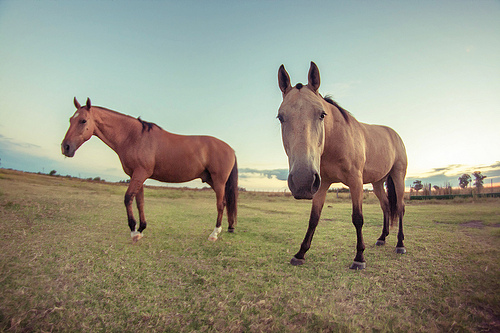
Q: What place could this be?
A: It is a field.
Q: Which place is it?
A: It is a field.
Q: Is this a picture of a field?
A: Yes, it is showing a field.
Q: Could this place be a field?
A: Yes, it is a field.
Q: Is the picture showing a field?
A: Yes, it is showing a field.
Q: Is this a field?
A: Yes, it is a field.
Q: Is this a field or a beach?
A: It is a field.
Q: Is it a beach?
A: No, it is a field.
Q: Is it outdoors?
A: Yes, it is outdoors.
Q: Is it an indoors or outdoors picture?
A: It is outdoors.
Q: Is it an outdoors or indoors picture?
A: It is outdoors.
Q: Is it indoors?
A: No, it is outdoors.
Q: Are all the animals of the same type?
A: Yes, all the animals are horses.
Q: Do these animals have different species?
A: No, all the animals are horses.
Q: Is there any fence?
A: No, there are no fences.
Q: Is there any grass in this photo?
A: Yes, there is grass.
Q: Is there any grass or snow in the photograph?
A: Yes, there is grass.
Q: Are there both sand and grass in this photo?
A: No, there is grass but no sand.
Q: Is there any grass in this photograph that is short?
A: Yes, there is short grass.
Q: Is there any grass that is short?
A: Yes, there is grass that is short.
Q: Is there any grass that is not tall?
A: Yes, there is short grass.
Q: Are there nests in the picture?
A: No, there are no nests.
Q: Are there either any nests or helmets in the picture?
A: No, there are no nests or helmets.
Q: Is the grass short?
A: Yes, the grass is short.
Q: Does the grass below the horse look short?
A: Yes, the grass is short.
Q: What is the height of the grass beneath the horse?
A: The grass is short.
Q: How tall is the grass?
A: The grass is short.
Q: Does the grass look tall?
A: No, the grass is short.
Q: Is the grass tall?
A: No, the grass is short.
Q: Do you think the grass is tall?
A: No, the grass is short.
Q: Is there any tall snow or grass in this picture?
A: No, there is grass but it is short.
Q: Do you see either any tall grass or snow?
A: No, there is grass but it is short.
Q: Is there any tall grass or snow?
A: No, there is grass but it is short.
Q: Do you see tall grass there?
A: No, there is grass but it is short.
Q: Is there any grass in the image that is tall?
A: No, there is grass but it is short.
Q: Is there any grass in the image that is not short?
A: No, there is grass but it is short.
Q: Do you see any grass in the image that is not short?
A: No, there is grass but it is short.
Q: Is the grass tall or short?
A: The grass is short.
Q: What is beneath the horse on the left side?
A: The grass is beneath the horse.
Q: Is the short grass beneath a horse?
A: Yes, the grass is beneath a horse.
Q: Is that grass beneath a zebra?
A: No, the grass is beneath a horse.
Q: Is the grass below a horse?
A: Yes, the grass is below a horse.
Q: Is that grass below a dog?
A: No, the grass is below a horse.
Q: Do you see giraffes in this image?
A: No, there are no giraffes.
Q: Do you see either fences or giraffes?
A: No, there are no giraffes or fences.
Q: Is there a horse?
A: Yes, there is a horse.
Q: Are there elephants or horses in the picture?
A: Yes, there is a horse.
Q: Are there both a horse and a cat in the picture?
A: No, there is a horse but no cats.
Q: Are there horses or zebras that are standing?
A: Yes, the horse is standing.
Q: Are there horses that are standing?
A: Yes, there is a horse that is standing.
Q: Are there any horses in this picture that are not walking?
A: Yes, there is a horse that is standing.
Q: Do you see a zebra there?
A: No, there are no zebras.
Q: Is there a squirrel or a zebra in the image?
A: No, there are no zebras or squirrels.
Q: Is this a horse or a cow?
A: This is a horse.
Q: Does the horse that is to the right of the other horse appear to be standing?
A: Yes, the horse is standing.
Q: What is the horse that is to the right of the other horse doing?
A: The horse is standing.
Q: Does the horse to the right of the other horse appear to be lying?
A: No, the horse is standing.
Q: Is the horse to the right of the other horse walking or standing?
A: The horse is standing.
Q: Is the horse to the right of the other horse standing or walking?
A: The horse is standing.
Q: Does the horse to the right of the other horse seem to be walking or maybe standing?
A: The horse is standing.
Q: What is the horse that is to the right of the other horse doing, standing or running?
A: The horse is standing.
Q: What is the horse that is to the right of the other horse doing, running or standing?
A: The horse is standing.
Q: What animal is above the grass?
A: The animal is a horse.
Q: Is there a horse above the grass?
A: Yes, there is a horse above the grass.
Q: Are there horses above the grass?
A: Yes, there is a horse above the grass.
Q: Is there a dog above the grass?
A: No, there is a horse above the grass.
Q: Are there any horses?
A: Yes, there are horses.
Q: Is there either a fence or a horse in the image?
A: Yes, there are horses.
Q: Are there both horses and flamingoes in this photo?
A: No, there are horses but no flamingoes.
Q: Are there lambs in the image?
A: No, there are no lambs.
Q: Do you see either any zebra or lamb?
A: No, there are no lambs or zebras.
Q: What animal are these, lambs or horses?
A: These are horses.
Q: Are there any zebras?
A: No, there are no zebras.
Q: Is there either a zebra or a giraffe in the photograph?
A: No, there are no zebras or giraffes.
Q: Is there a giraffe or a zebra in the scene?
A: No, there are no zebras or giraffes.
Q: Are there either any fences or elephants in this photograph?
A: No, there are no fences or elephants.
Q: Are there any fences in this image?
A: No, there are no fences.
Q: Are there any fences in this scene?
A: No, there are no fences.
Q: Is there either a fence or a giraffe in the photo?
A: No, there are no fences or giraffes.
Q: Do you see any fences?
A: No, there are no fences.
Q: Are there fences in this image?
A: No, there are no fences.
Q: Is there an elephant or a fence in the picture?
A: No, there are no fences or elephants.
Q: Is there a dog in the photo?
A: No, there are no dogs.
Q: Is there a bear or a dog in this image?
A: No, there are no dogs or bears.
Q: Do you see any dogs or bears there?
A: No, there are no dogs or bears.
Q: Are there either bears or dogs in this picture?
A: No, there are no dogs or bears.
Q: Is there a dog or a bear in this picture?
A: No, there are no dogs or bears.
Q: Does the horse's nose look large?
A: Yes, the nose is large.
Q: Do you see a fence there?
A: No, there are no fences.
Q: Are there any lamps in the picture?
A: No, there are no lamps.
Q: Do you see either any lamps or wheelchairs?
A: No, there are no lamps or wheelchairs.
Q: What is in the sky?
A: The clouds are in the sky.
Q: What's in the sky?
A: The clouds are in the sky.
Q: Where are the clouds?
A: The clouds are in the sky.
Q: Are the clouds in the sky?
A: Yes, the clouds are in the sky.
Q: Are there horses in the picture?
A: Yes, there is a horse.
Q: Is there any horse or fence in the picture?
A: Yes, there is a horse.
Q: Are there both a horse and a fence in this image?
A: No, there is a horse but no fences.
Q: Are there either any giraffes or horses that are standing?
A: Yes, the horse is standing.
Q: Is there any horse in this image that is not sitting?
A: Yes, there is a horse that is standing.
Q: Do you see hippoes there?
A: No, there are no hippoes.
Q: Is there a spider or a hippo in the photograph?
A: No, there are no hippoes or spiders.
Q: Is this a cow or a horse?
A: This is a horse.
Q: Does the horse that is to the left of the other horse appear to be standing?
A: Yes, the horse is standing.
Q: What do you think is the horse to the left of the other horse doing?
A: The horse is standing.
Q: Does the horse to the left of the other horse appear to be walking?
A: No, the horse is standing.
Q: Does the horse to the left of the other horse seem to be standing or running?
A: The horse is standing.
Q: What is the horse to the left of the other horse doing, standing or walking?
A: The horse is standing.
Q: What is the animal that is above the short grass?
A: The animal is a horse.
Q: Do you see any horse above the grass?
A: Yes, there is a horse above the grass.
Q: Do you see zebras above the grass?
A: No, there is a horse above the grass.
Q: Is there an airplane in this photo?
A: No, there are no airplanes.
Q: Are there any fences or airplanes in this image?
A: No, there are no airplanes or fences.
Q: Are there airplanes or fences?
A: No, there are no airplanes or fences.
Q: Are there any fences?
A: No, there are no fences.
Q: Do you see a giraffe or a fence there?
A: No, there are no fences or giraffes.